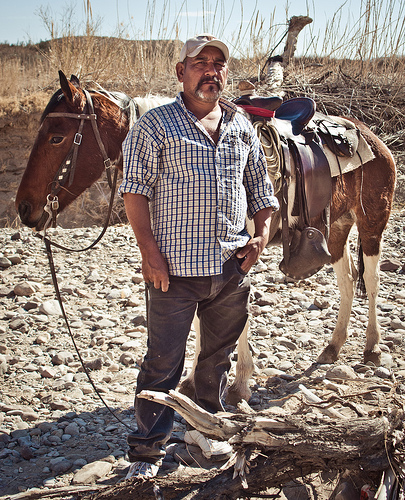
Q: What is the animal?
A: A horse.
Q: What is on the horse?
A: A saddle.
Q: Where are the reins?
A: Under his foot.